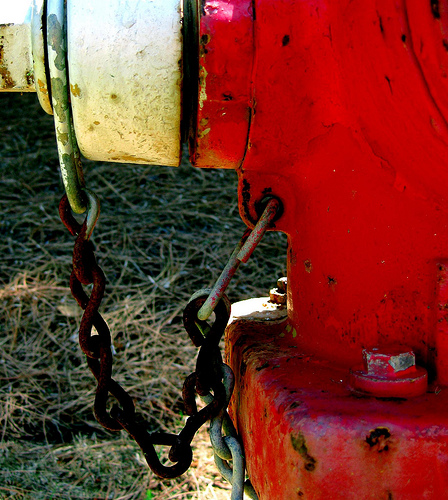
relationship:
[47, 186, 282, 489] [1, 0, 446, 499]
chain on fire hydrant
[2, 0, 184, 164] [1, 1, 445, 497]
arm of hydrant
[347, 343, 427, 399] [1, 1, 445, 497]
nut on hydrant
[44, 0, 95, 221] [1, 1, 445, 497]
ring on hydrant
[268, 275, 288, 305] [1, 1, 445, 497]
bolt on hydrant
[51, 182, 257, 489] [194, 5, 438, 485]
chain hanging from hydrant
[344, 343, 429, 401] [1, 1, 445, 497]
cap on a fire hydrant